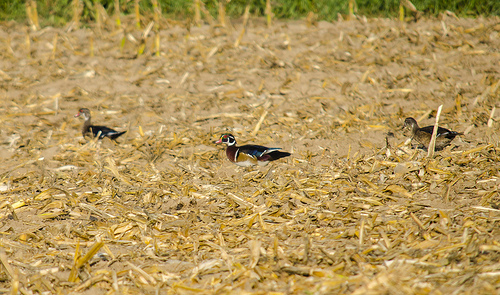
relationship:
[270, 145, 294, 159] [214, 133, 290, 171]
tail of bird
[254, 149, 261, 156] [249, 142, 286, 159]
section of duck wing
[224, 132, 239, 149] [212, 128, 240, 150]
stripes on head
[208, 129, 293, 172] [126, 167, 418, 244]
bird walking in wood chips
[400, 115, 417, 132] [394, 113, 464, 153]
hace of bird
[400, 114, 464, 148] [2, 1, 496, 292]
bird on ground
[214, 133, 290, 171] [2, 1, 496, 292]
bird on ground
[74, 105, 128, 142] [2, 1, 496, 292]
bird on ground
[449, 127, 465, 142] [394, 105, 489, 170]
tail of bird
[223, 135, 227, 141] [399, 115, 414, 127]
redeye on duck face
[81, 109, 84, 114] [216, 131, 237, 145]
redeye on duck face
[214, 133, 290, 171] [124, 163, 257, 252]
bird on straw